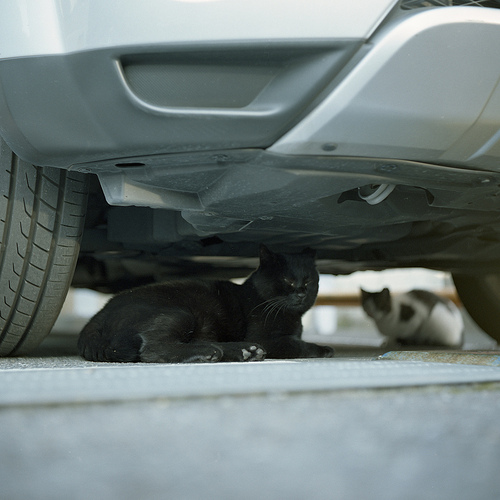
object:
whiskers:
[248, 296, 291, 331]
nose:
[297, 282, 306, 299]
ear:
[297, 245, 317, 262]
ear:
[360, 286, 370, 298]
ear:
[381, 287, 390, 297]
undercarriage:
[96, 160, 483, 256]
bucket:
[315, 305, 345, 345]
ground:
[313, 332, 350, 347]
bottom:
[119, 148, 496, 265]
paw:
[242, 345, 267, 360]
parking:
[80, 371, 495, 454]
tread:
[0, 138, 92, 357]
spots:
[400, 302, 416, 322]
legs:
[140, 317, 224, 363]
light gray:
[118, 50, 289, 109]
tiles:
[80, 235, 332, 376]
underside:
[82, 160, 499, 243]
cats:
[77, 242, 334, 363]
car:
[0, 1, 499, 358]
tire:
[0, 139, 90, 357]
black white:
[359, 284, 466, 350]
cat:
[360, 287, 465, 350]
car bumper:
[2, 0, 500, 249]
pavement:
[0, 284, 499, 500]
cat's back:
[395, 289, 458, 318]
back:
[386, 277, 459, 364]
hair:
[260, 251, 317, 270]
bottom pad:
[209, 330, 274, 403]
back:
[392, 285, 471, 367]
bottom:
[233, 336, 274, 382]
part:
[43, 379, 491, 482]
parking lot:
[0, 285, 498, 499]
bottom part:
[17, 31, 392, 187]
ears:
[259, 242, 275, 265]